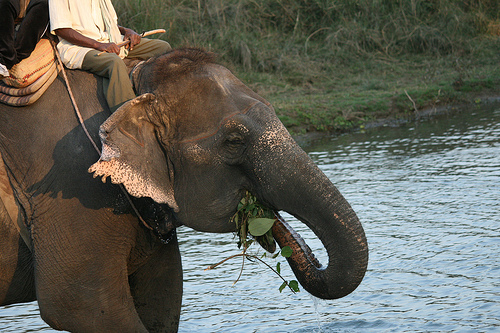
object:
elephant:
[0, 48, 371, 332]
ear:
[88, 87, 184, 213]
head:
[89, 45, 297, 235]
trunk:
[265, 133, 370, 302]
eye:
[223, 130, 247, 152]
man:
[44, 0, 175, 115]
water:
[0, 104, 499, 331]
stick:
[94, 29, 169, 57]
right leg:
[79, 48, 139, 115]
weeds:
[233, 193, 284, 263]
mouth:
[234, 187, 297, 249]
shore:
[102, 0, 500, 142]